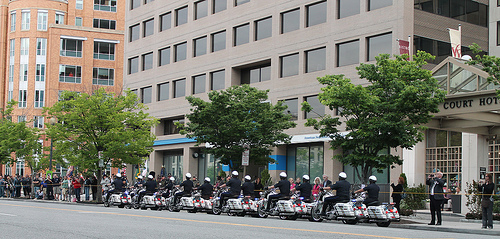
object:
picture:
[0, 0, 499, 238]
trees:
[38, 84, 297, 177]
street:
[0, 199, 499, 238]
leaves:
[100, 89, 140, 140]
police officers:
[213, 171, 351, 209]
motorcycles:
[99, 188, 402, 228]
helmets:
[278, 171, 311, 179]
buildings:
[3, 0, 500, 223]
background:
[0, 0, 499, 90]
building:
[249, 0, 500, 174]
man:
[421, 170, 445, 224]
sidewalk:
[393, 198, 500, 236]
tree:
[301, 49, 448, 184]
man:
[331, 173, 350, 201]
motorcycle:
[312, 200, 366, 224]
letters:
[440, 97, 498, 109]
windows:
[126, 9, 228, 76]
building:
[1, 0, 129, 174]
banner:
[445, 25, 465, 61]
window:
[212, 29, 229, 52]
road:
[0, 197, 499, 238]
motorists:
[339, 171, 382, 203]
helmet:
[369, 174, 380, 181]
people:
[238, 172, 381, 208]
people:
[22, 171, 99, 203]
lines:
[0, 200, 129, 224]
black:
[336, 186, 348, 197]